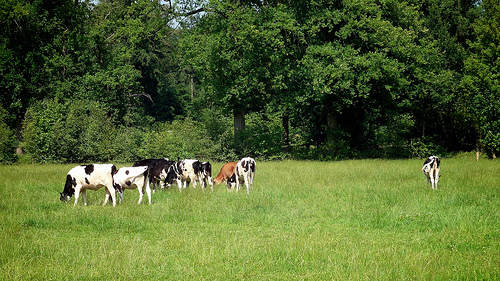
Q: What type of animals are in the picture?
A: Cows.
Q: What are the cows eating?
A: Grass.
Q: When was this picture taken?
A: Daytime.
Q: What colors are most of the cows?
A: Black and white.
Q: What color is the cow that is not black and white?
A: Brown.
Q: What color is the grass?
A: Green.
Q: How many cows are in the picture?
A: 8.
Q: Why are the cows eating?
A: They're hungry.